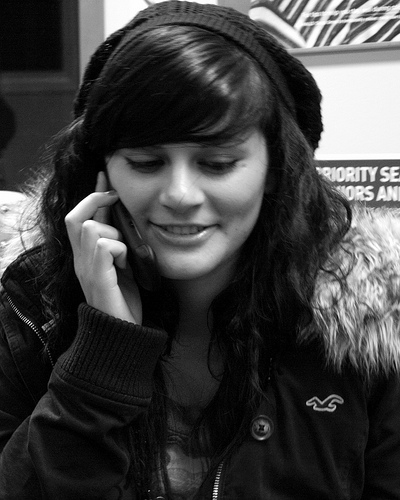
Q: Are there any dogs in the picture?
A: No, there are no dogs.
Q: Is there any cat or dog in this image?
A: No, there are no dogs or cats.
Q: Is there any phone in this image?
A: Yes, there is a phone.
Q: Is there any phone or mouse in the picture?
A: Yes, there is a phone.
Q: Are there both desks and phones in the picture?
A: No, there is a phone but no desks.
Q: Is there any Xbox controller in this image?
A: No, there are no Xbox controllers.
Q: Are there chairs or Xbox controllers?
A: No, there are no Xbox controllers or chairs.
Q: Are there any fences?
A: No, there are no fences.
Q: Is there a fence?
A: No, there are no fences.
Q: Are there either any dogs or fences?
A: No, there are no fences or dogs.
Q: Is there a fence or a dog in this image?
A: No, there are no fences or dogs.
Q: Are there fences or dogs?
A: No, there are no fences or dogs.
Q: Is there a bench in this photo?
A: No, there are no benches.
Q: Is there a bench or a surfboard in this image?
A: No, there are no benches or surfboards.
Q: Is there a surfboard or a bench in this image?
A: No, there are no benches or surfboards.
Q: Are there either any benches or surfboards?
A: No, there are no benches or surfboards.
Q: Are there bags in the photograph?
A: No, there are no bags.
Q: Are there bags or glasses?
A: No, there are no bags or glasses.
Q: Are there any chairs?
A: No, there are no chairs.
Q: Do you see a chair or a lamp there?
A: No, there are no chairs or lamps.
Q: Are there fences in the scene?
A: No, there are no fences.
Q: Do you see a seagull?
A: Yes, there is a seagull.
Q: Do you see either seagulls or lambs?
A: Yes, there is a seagull.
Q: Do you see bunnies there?
A: No, there are no bunnies.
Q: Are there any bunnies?
A: No, there are no bunnies.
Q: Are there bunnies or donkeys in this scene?
A: No, there are no bunnies or donkeys.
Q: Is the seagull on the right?
A: Yes, the seagull is on the right of the image.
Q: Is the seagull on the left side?
A: No, the seagull is on the right of the image.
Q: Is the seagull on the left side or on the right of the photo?
A: The seagull is on the right of the image.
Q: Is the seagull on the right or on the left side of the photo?
A: The seagull is on the right of the image.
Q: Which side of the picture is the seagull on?
A: The seagull is on the right of the image.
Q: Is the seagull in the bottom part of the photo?
A: Yes, the seagull is in the bottom of the image.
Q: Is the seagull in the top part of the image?
A: No, the seagull is in the bottom of the image.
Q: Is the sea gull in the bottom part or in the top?
A: The sea gull is in the bottom of the image.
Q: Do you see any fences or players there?
A: No, there are no fences or players.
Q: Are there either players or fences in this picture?
A: No, there are no fences or players.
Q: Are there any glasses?
A: No, there are no glasses.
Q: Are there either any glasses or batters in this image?
A: No, there are no glasses or batters.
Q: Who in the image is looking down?
A: The girl is looking down.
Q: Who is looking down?
A: The girl is looking down.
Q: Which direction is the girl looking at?
A: The girl is looking down.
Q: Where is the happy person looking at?
A: The girl is looking down.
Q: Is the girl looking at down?
A: Yes, the girl is looking down.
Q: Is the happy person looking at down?
A: Yes, the girl is looking down.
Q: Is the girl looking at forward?
A: No, the girl is looking down.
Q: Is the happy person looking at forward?
A: No, the girl is looking down.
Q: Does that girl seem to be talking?
A: Yes, the girl is talking.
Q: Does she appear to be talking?
A: Yes, the girl is talking.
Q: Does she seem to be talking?
A: Yes, the girl is talking.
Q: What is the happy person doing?
A: The girl is talking.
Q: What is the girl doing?
A: The girl is talking.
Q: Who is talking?
A: The girl is talking.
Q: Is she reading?
A: No, the girl is talking.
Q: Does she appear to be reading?
A: No, the girl is talking.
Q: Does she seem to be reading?
A: No, the girl is talking.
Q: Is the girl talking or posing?
A: The girl is talking.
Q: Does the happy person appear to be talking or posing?
A: The girl is talking.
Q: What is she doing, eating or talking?
A: The girl is talking.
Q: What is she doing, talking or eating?
A: The girl is talking.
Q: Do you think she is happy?
A: Yes, the girl is happy.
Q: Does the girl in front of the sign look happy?
A: Yes, the girl is happy.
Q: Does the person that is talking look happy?
A: Yes, the girl is happy.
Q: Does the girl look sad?
A: No, the girl is happy.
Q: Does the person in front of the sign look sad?
A: No, the girl is happy.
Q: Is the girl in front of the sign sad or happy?
A: The girl is happy.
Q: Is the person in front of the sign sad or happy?
A: The girl is happy.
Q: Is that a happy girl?
A: Yes, that is a happy girl.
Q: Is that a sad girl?
A: No, that is a happy girl.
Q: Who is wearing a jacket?
A: The girl is wearing a jacket.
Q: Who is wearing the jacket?
A: The girl is wearing a jacket.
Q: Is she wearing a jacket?
A: Yes, the girl is wearing a jacket.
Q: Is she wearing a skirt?
A: No, the girl is wearing a jacket.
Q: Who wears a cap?
A: The girl wears a cap.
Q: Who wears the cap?
A: The girl wears a cap.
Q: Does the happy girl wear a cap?
A: Yes, the girl wears a cap.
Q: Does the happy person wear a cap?
A: Yes, the girl wears a cap.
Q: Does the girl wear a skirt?
A: No, the girl wears a cap.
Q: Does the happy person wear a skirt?
A: No, the girl wears a cap.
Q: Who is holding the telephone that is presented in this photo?
A: The girl is holding the telephone.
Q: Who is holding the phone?
A: The girl is holding the telephone.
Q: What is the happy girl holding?
A: The girl is holding the telephone.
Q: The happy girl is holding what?
A: The girl is holding the telephone.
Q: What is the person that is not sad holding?
A: The girl is holding the telephone.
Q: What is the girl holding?
A: The girl is holding the telephone.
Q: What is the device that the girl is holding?
A: The device is a phone.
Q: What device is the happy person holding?
A: The girl is holding the phone.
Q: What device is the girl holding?
A: The girl is holding the phone.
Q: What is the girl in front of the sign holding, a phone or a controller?
A: The girl is holding a phone.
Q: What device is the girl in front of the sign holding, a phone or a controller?
A: The girl is holding a phone.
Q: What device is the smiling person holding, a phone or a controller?
A: The girl is holding a phone.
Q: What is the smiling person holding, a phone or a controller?
A: The girl is holding a phone.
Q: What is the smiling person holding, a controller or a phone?
A: The girl is holding a phone.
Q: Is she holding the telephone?
A: Yes, the girl is holding the telephone.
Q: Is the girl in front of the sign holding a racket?
A: No, the girl is holding the telephone.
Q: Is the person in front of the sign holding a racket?
A: No, the girl is holding the telephone.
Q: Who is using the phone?
A: The girl is using the phone.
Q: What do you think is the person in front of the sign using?
A: The girl is using a phone.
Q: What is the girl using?
A: The girl is using a phone.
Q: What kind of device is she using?
A: The girl is using a telephone.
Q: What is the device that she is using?
A: The device is a phone.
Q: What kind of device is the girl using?
A: The girl is using a telephone.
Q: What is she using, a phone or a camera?
A: The girl is using a phone.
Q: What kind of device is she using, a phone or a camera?
A: The girl is using a phone.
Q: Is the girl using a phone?
A: Yes, the girl is using a phone.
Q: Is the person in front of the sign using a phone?
A: Yes, the girl is using a phone.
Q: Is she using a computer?
A: No, the girl is using a phone.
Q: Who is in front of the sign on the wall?
A: The girl is in front of the sign.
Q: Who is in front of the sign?
A: The girl is in front of the sign.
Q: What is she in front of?
A: The girl is in front of the sign.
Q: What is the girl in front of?
A: The girl is in front of the sign.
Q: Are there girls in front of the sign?
A: Yes, there is a girl in front of the sign.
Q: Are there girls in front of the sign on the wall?
A: Yes, there is a girl in front of the sign.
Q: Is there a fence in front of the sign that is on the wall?
A: No, there is a girl in front of the sign.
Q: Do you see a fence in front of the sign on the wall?
A: No, there is a girl in front of the sign.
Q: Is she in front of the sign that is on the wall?
A: Yes, the girl is in front of the sign.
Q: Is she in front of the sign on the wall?
A: Yes, the girl is in front of the sign.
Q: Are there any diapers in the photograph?
A: No, there are no diapers.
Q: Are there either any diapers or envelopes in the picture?
A: No, there are no diapers or envelopes.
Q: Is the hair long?
A: Yes, the hair is long.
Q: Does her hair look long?
A: Yes, the hair is long.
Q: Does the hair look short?
A: No, the hair is long.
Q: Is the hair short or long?
A: The hair is long.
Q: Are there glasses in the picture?
A: No, there are no glasses.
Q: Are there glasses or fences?
A: No, there are no glasses or fences.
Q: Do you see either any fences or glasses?
A: No, there are no glasses or fences.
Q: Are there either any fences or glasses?
A: No, there are no glasses or fences.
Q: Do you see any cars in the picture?
A: No, there are no cars.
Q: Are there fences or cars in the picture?
A: No, there are no cars or fences.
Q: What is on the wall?
A: The sign is on the wall.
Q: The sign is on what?
A: The sign is on the wall.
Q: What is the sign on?
A: The sign is on the wall.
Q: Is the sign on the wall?
A: Yes, the sign is on the wall.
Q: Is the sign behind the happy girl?
A: Yes, the sign is behind the girl.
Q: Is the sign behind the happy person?
A: Yes, the sign is behind the girl.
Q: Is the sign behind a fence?
A: No, the sign is behind the girl.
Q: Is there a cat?
A: No, there are no cats.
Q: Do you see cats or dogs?
A: No, there are no cats or dogs.